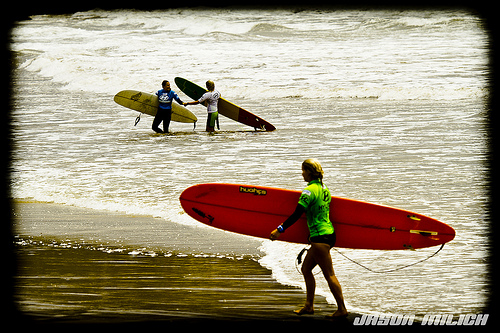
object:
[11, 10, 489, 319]
waves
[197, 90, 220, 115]
shirt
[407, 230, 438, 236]
fins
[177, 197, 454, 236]
line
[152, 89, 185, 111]
shirt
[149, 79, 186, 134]
man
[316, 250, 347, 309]
leg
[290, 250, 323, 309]
leg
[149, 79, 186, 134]
people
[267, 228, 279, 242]
hands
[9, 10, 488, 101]
bubbles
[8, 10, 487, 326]
water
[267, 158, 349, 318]
person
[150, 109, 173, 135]
black pants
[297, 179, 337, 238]
green shirt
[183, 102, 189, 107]
hands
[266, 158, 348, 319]
girl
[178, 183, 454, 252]
longboard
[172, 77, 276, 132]
surfboards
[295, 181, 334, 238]
many circles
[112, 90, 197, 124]
surfboard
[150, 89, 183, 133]
wetsuit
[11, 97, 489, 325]
beach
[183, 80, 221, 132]
person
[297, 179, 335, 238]
shirt